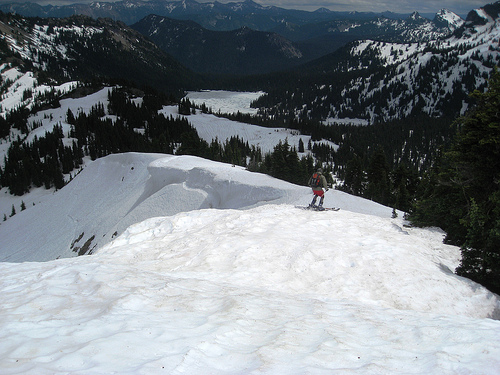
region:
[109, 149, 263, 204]
A large snow drift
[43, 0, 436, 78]
a distant mountain range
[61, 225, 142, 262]
a snow covered rock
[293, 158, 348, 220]
a skier on top of a hill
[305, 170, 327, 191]
a red and black backpack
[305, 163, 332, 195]
a grey ski jacket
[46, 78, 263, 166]
a forest of evergreens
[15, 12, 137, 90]
a snow covered mountainside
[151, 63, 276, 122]
an open valley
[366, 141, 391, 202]
a tree with thick foliage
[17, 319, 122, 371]
Snow covering the ground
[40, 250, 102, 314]
Snow covering the ground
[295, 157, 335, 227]
PErson in the snow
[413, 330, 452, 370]
Snow covering the ground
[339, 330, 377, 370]
Snow covering the ground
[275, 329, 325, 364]
Snow covering the ground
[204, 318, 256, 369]
Snow covering the ground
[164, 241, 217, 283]
Snow covering the ground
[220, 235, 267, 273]
Snow covering the ground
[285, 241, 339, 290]
Snow covering the ground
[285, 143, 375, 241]
this is a person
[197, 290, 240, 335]
this is snow on the ground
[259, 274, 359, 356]
this is snow on the ground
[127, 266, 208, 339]
this is snow on the ground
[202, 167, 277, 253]
this is snow on the ground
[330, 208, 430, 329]
this is snow on the ground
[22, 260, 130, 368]
this is snow on the ground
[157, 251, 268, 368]
this is snow on the ground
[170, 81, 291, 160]
this is snow on the ground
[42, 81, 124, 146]
this is snow on the ground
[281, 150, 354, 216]
This person is skiing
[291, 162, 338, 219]
The person is holding ski poles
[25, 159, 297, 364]
The mountain is covered in snow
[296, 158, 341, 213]
The person is wearing a backpack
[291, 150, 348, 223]
The person is going downhill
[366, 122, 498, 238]
A group of trees not covered by snow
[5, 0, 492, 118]
Large mountain range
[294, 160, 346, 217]
The person is wearing a jacket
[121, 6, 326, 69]
The mountains in the distance have no snow on them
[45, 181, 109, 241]
There is a line going through the snow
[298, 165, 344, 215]
person wearing back pack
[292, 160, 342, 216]
person looking at the top of the hill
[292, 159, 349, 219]
person on a pair of ski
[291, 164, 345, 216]
person wearing a hat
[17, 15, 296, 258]
a view of the mountain and snowy field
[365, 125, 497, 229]
bunch of pine trees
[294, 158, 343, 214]
person wearing a gray jacket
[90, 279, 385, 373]
a snowy field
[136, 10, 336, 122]
mountain ranges and snowy fields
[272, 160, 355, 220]
person trying to ski down